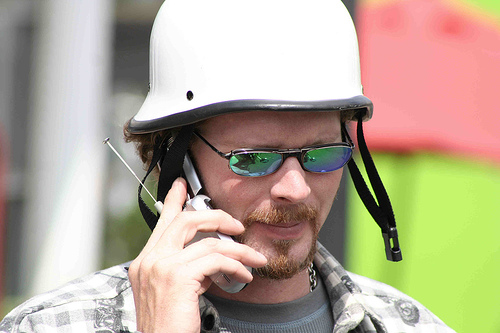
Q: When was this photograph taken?
A: Daytime.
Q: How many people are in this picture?
A: 1.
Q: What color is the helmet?
A: White.